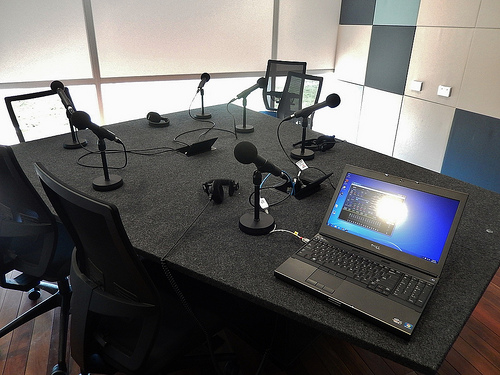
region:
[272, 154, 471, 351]
laptop on a desk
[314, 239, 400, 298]
keyboard on a laptop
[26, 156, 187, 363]
chair by a desk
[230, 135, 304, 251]
microphone on a table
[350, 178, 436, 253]
illuminated screen of a laptop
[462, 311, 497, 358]
wooden floor of an office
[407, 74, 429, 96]
thermostat mounted on the wall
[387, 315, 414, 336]
laptop brand on the computer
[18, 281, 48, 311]
wheel of a chair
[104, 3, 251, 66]
wall of an office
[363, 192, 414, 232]
reflection of light on the screen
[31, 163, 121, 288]
a black chair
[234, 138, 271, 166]
a black mircrophone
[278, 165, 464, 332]
a laptop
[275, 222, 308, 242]
a cord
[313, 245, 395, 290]
the keyboard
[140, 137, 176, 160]
cords on the table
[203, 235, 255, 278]
the table is black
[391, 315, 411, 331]
stickers on the laptop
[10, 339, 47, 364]
the wooden floor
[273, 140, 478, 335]
a laptop is open & ready to go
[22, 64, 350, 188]
a desk full of microphones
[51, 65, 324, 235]
the microphones are black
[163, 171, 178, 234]
the top of the table is dark grey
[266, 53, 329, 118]
the chairs appear to have a mesh back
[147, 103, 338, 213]
several sets of headphones are on the table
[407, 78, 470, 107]
boxes on the wall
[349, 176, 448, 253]
the screen is mainly blue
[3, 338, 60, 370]
the floor is made of wood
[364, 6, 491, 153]
the wall is made of large tiles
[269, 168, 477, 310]
black laptop sitting on table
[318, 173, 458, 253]
screen of lap top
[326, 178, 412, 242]
document open on screen of laptop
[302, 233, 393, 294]
black keyboard of lap top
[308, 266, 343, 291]
black track pad of lap top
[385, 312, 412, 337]
logo on bottom left of lap top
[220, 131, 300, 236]
black microphone on table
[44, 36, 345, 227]
many black microphones on table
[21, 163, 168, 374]
black chair next to table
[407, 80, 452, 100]
white light switches on the wall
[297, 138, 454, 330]
BLACK LAPTOP ON TABLE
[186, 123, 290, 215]
BLACK MICROPHONE ON TABLE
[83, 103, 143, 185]
BLACK MICROPHONE ON TABLE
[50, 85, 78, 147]
BLACK MICROPHONE ON TABLE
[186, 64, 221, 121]
BLACK MICROPHONE ON TABLE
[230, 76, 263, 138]
BLACK MICROPHONE ON TABLE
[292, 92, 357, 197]
BLACK MICROPHONE ON TABLE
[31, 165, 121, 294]
BLACK CHAIR AT TABLE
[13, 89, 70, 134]
SMALL CHAIR AT WINDOW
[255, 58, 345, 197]
TWO CHAIRS AT TABLE